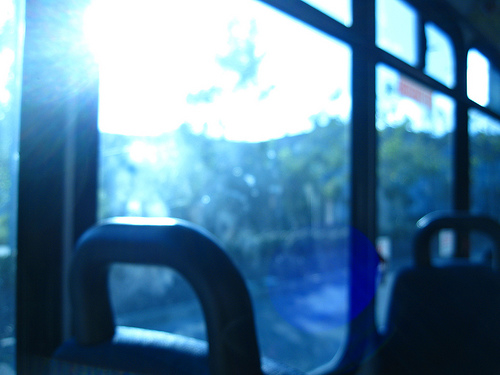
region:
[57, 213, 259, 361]
black head rest of seat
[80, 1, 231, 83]
sun shinning thru window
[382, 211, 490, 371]
black seat of bus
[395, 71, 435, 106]
red and white sticker on window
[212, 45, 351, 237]
window beside black seat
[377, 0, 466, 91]
two smaller windows at top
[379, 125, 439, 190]
green trees outside of window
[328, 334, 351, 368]
rubber grommet holding window in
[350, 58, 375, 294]
black metal separating windows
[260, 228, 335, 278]
row of shrubs outside window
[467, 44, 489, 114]
Small window on a bus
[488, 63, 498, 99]
Small window on a bus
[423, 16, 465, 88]
Small window on a bus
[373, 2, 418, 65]
Small window on a bus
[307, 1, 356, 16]
Small window on a bus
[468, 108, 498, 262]
Small window on a bus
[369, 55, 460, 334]
Small window on a bus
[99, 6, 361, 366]
Small window on a bus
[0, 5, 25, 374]
Small window on a bus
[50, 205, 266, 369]
Small head rest in a bus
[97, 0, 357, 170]
sun brightly reflected in window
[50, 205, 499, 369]
the backs of two visible train seats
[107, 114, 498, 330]
forest seen through train windows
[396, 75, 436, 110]
small sticker in train window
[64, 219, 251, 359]
rounded headrest with open back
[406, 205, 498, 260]
rounded headrest with open back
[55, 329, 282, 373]
padded train seat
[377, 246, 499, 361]
padded train seat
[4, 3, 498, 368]
interior of train on sunny day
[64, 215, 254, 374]
The chair is dark in color.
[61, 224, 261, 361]
The chair is made of plastic.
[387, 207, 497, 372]
The chair is black.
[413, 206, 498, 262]
The head of the chair is made of plastic.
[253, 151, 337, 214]
The trees in the background are green.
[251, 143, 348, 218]
The trees in the background are blurry.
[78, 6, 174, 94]
The sun is shining through the glass.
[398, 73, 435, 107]
The sign on the window is red.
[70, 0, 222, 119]
the sky is bright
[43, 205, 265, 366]
head rest of chair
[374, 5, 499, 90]
a row of small windows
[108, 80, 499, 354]
row of large windows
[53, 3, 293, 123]
glare on the window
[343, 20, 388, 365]
trim on the window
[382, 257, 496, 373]
back of a chair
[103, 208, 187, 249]
reflection on head rest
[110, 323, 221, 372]
top of the seat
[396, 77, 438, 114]
sign on the window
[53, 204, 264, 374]
hand rail on back of chair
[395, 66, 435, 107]
sticker in middle window